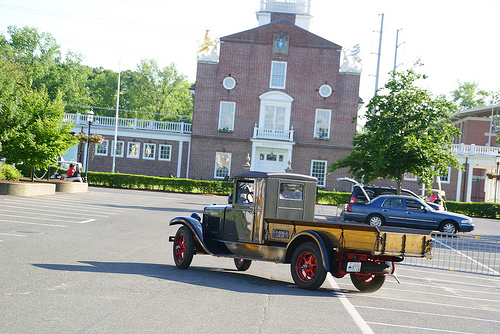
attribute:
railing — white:
[62, 101, 192, 136]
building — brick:
[67, 12, 492, 202]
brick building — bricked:
[135, 8, 405, 206]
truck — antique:
[166, 165, 436, 294]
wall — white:
[198, 24, 360, 145]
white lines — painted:
[309, 257, 499, 331]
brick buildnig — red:
[64, 0, 499, 208]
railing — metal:
[393, 231, 498, 276]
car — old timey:
[166, 160, 434, 296]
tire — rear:
[288, 241, 325, 284]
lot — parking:
[0, 183, 484, 332]